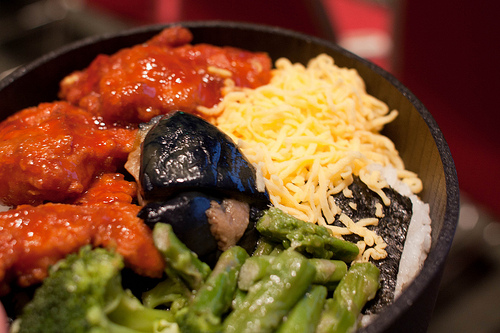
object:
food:
[137, 111, 267, 265]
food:
[9, 248, 345, 333]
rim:
[209, 25, 464, 333]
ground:
[376, 178, 401, 207]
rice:
[368, 161, 431, 301]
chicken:
[57, 25, 270, 124]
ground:
[463, 56, 499, 192]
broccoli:
[16, 244, 171, 333]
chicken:
[0, 100, 161, 290]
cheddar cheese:
[199, 54, 424, 265]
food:
[0, 23, 430, 333]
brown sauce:
[203, 199, 249, 252]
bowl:
[0, 20, 460, 333]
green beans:
[180, 235, 378, 333]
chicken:
[5, 23, 268, 275]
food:
[22, 208, 375, 333]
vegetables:
[21, 238, 386, 333]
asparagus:
[16, 209, 381, 333]